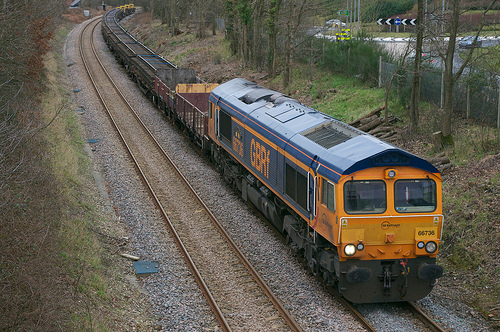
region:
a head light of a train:
[382, 167, 399, 181]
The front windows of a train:
[340, 173, 440, 218]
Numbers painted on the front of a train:
[411, 222, 439, 239]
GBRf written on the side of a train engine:
[244, 131, 276, 185]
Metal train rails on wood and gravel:
[151, 193, 226, 239]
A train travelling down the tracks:
[184, 62, 462, 317]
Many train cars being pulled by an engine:
[95, 5, 180, 96]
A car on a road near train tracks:
[454, 32, 484, 52]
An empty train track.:
[120, 135, 190, 207]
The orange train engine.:
[213, 75, 446, 307]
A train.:
[102, 7, 448, 299]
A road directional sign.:
[376, 12, 421, 27]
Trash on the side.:
[122, 246, 164, 278]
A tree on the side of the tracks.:
[419, 12, 466, 144]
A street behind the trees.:
[381, 40, 496, 64]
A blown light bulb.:
[424, 241, 437, 253]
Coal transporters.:
[118, 32, 155, 67]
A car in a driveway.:
[327, 17, 351, 27]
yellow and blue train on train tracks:
[131, 45, 461, 319]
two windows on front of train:
[335, 170, 440, 217]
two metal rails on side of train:
[297, 165, 323, 221]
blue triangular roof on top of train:
[210, 70, 442, 184]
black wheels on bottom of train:
[210, 146, 340, 298]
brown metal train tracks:
[62, 10, 304, 330]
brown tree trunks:
[404, 2, 481, 150]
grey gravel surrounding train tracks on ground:
[60, 30, 347, 330]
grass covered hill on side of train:
[121, 8, 497, 321]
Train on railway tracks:
[102, 13, 460, 312]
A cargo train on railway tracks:
[103, 1, 463, 301]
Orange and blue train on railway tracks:
[98, 10, 452, 310]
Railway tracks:
[100, 99, 229, 327]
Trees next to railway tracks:
[240, 8, 482, 329]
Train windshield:
[332, 171, 439, 223]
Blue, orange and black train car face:
[324, 131, 451, 318]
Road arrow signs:
[370, 10, 420, 39]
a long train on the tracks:
[207, 86, 421, 261]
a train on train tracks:
[125, 12, 452, 323]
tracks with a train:
[127, 43, 389, 320]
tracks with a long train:
[150, 111, 432, 321]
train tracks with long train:
[85, 11, 343, 276]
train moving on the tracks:
[85, 51, 387, 315]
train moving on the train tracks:
[155, 21, 485, 326]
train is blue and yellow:
[205, 76, 446, 306]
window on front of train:
[343, 177, 385, 211]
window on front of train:
[393, 180, 436, 215]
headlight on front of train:
[418, 240, 437, 251]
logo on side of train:
[247, 139, 272, 179]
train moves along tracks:
[101, 3, 444, 310]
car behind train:
[324, 17, 346, 27]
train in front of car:
[100, 1, 445, 307]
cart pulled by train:
[174, 82, 219, 152]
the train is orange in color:
[211, 75, 443, 307]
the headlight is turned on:
[343, 240, 354, 255]